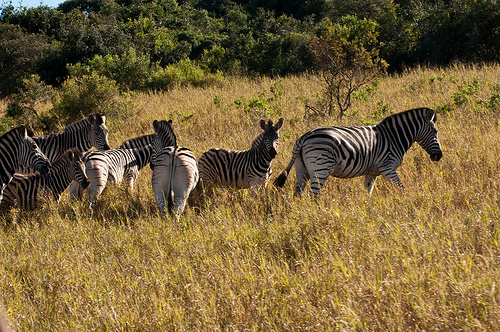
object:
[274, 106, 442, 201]
zebra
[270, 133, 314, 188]
tail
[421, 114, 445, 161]
face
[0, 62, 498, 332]
grass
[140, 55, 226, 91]
bushes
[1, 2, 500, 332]
background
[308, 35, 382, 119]
tree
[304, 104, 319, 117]
branch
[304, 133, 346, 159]
stripe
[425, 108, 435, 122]
ear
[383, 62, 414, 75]
shadow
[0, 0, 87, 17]
sky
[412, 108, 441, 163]
head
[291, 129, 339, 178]
back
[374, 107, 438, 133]
mane